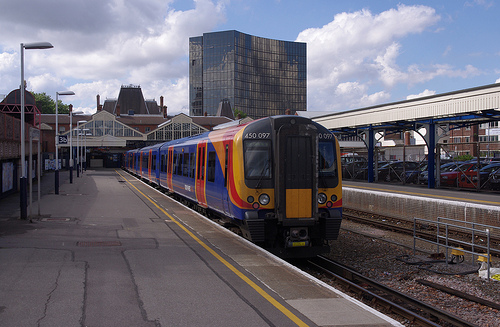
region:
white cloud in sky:
[309, 23, 347, 57]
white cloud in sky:
[331, 66, 366, 113]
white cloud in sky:
[373, 53, 405, 97]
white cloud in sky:
[414, 55, 454, 86]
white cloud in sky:
[401, 5, 442, 58]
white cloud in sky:
[374, 15, 399, 45]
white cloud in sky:
[168, 5, 225, 42]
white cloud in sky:
[139, 28, 176, 68]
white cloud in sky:
[105, 42, 140, 92]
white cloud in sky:
[64, 40, 124, 75]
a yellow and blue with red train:
[119, 108, 339, 243]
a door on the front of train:
[286, 130, 313, 221]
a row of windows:
[169, 151, 216, 178]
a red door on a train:
[190, 143, 208, 205]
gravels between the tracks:
[348, 243, 403, 264]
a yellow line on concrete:
[176, 217, 250, 293]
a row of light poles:
[15, 36, 96, 228]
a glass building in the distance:
[193, 28, 308, 110]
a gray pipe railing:
[415, 212, 494, 252]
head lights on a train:
[249, 187, 331, 215]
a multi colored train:
[114, 116, 380, 266]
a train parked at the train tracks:
[116, 106, 473, 326]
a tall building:
[174, 31, 409, 188]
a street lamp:
[15, 24, 57, 226]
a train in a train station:
[63, 96, 364, 323]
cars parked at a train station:
[319, 98, 475, 195]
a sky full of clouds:
[22, 9, 486, 109]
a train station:
[31, 102, 263, 187]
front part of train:
[227, 95, 339, 247]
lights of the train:
[245, 180, 277, 214]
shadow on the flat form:
[128, 176, 285, 321]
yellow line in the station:
[188, 225, 301, 320]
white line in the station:
[304, 255, 366, 314]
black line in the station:
[124, 257, 151, 318]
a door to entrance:
[186, 139, 216, 226]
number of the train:
[226, 105, 280, 147]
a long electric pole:
[13, 37, 73, 246]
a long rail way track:
[334, 270, 461, 324]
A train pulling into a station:
[112, 107, 350, 262]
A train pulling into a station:
[106, 108, 351, 265]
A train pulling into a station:
[114, 109, 350, 266]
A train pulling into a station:
[114, 106, 346, 258]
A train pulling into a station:
[114, 112, 347, 262]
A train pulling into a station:
[118, 105, 347, 261]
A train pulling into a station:
[123, 108, 351, 260]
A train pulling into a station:
[121, 110, 347, 262]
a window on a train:
[312, 135, 335, 171]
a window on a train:
[248, 140, 274, 180]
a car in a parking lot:
[470, 165, 495, 187]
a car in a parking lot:
[439, 162, 477, 190]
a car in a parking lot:
[401, 162, 426, 187]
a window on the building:
[253, 66, 275, 86]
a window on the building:
[283, 61, 297, 78]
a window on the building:
[277, 98, 287, 108]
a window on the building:
[237, 85, 268, 120]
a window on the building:
[289, 56, 301, 74]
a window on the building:
[289, 93, 304, 114]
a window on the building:
[247, 96, 268, 122]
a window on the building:
[216, 67, 246, 96]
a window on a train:
[319, 135, 340, 185]